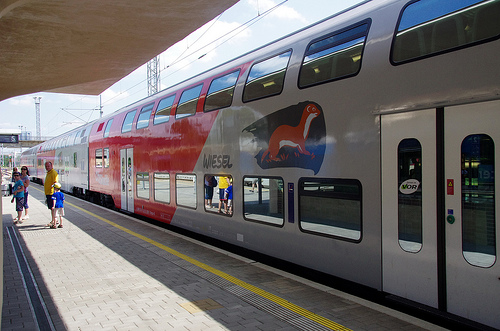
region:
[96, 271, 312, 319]
a brick side walk with a yellow line.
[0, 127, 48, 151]
a white bridge.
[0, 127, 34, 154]
a black sign with the number 5.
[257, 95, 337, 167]
a red and white animal.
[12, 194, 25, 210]
a man is wearing black jean shorts.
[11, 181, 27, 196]
a man is wearing a blue shirt.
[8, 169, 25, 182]
a man is wearing glasses.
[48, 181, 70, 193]
a little boy is wearing a hat.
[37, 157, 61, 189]
a man is wearing a yellow shirt.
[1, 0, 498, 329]
a big train is rideing down the tracks.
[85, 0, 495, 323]
a double decker train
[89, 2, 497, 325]
a silver and red train passenger car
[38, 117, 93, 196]
a silver and red train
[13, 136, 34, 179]
a silver and red train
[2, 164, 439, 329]
a passenger boarding platform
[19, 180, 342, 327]
a long yellow stripe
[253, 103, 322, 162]
graphic of a ferret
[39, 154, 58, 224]
a man standing on platform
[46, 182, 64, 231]
a young boy on platform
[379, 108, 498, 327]
a set of train doors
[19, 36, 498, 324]
A long passenger train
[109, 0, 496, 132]
windows on a passenger train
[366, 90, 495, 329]
doors on a passenger train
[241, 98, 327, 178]
A weasel painted on a train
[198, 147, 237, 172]
A word that says Wiesel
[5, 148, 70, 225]
A family waiting by the train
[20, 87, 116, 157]
Electrical lines in the distance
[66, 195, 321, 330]
A yellow line on the sidewalk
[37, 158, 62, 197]
A man in a yellow shirt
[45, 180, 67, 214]
A boy in a blue shirt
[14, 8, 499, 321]
a double decker train is in the station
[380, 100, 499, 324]
double doors are on the train car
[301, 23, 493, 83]
seats in the sightseeing section of the train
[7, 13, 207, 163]
an overhang in the train terminal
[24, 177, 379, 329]
a yellow line is along the platform edge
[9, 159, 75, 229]
a family is waiting for the train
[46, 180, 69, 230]
the child has a cap on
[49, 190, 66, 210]
a blue shirt is on the child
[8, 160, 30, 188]
the lady is holding a baby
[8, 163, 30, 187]
the lady and the boy are wearing sunglasses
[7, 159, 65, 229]
Passengers from a train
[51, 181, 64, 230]
A little boy standing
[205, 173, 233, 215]
Reflection in the train window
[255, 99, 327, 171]
A drawing of a wiesel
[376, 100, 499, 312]
The doors of a train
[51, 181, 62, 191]
A cap on a boy's head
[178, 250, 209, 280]
A yellow line on the floor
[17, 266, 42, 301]
Two white lines on the floor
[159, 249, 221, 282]
Shadow cast by the train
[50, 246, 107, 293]
Reflection by the sun on the floor